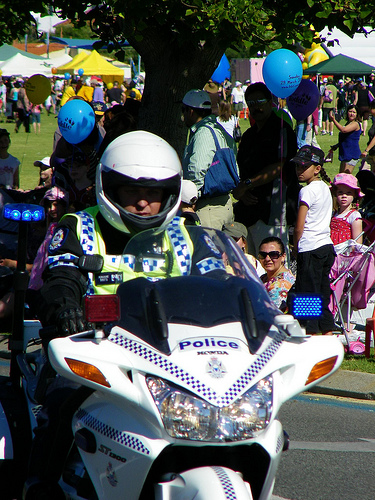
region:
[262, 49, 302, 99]
A floating, blue balloon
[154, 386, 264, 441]
Front headlight on a motorcycle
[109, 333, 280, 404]
Checkered stripe on a motorcycle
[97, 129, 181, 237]
A white motorcycle helmet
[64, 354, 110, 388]
Turning signal on a motorcycle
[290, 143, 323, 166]
Black hat on a girl's head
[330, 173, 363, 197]
Pink hat on a girl's head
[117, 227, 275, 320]
Windshield on the front of a motorcycle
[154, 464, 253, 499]
Front fender on a white motorcycle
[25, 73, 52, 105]
Yellow balloon floating on a string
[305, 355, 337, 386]
A small light on a motorcycle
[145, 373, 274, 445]
Front headlight of a motor bike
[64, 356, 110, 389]
An orange light on a vehicle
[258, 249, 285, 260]
A pair of sunglasses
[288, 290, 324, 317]
Blue light on a motorcycle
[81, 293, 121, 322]
A red light on a motorbike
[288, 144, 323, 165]
A hat on a kid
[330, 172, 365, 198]
A pink bucket hat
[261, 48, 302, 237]
A blue balloon on a string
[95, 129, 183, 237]
A white helmet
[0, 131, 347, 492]
a police officer on motorcycle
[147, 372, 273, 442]
a motorcycle front headlight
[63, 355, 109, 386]
a motorcycle turn signal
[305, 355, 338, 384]
a motorcycle turn signal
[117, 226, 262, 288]
a motorcycle front windshield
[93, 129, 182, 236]
a motorcycle white helmet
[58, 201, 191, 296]
a fluorescent safety vest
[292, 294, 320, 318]
a blue emergency light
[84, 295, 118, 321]
a red emergency light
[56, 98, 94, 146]
an inflated blue balloon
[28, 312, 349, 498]
a white and blue motorcycle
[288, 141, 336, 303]
girl wears white shirt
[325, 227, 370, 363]
the stroller is pink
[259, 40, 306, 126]
balloon is color blue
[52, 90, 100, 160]
the balloon is blue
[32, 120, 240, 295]
police officer wears white helmet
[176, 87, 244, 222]
person holding a blue bag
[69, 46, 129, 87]
the awning is color yellow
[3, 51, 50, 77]
the awning is color white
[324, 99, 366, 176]
woman wears blue top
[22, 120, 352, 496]
a police officer on motorcycle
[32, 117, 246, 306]
a police officer wears white helmet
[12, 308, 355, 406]
the handles of motorcycle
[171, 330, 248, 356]
word POLICE on front of motorcycle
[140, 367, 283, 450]
a headlight on front of motorcycle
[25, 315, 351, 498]
motorcycle is color white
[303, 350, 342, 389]
the light is orange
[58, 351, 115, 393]
the light is orange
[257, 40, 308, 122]
the balloon is color blue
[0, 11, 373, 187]
many people in fair